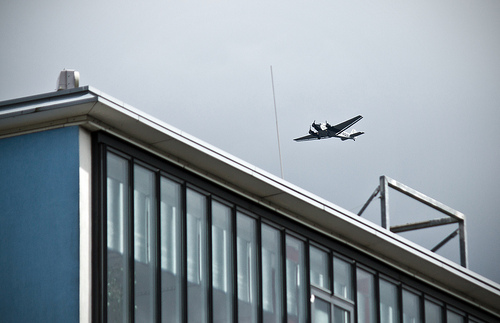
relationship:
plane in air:
[293, 112, 366, 142] [175, 75, 359, 120]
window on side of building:
[229, 178, 283, 316] [115, 180, 326, 320]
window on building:
[172, 194, 196, 297] [7, 63, 497, 322]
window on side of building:
[131, 162, 162, 321] [7, 63, 497, 322]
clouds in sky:
[334, 25, 433, 94] [6, 5, 498, 119]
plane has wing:
[293, 112, 366, 142] [332, 113, 365, 128]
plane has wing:
[293, 112, 366, 142] [288, 132, 311, 143]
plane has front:
[293, 112, 366, 142] [306, 115, 327, 135]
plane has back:
[293, 112, 366, 142] [337, 128, 367, 146]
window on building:
[161, 177, 185, 322] [7, 63, 497, 322]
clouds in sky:
[295, 23, 427, 83] [0, 2, 497, 232]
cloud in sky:
[6, 4, 498, 274] [14, 1, 474, 291]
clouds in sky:
[255, 52, 372, 104] [25, 19, 475, 232]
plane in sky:
[293, 112, 366, 142] [14, 1, 474, 291]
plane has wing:
[293, 112, 366, 142] [331, 112, 364, 132]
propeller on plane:
[306, 117, 318, 129] [285, 100, 372, 152]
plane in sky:
[293, 112, 366, 142] [1, 1, 499, 272]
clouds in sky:
[136, 23, 393, 95] [2, 3, 498, 210]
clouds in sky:
[300, 4, 499, 112] [2, 3, 498, 210]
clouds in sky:
[181, 17, 262, 67] [294, 6, 411, 58]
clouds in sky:
[135, 18, 247, 81] [2, 3, 498, 210]